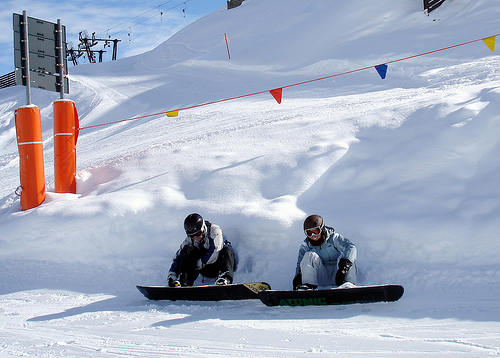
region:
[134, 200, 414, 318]
two snowboarders dismounting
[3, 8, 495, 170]
ski lift in ski area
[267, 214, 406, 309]
woman adjusts snowboard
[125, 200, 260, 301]
man adjusts snowboard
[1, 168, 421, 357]
couple adjusting snowboards in groomed snow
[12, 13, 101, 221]
rear view of sign in ski area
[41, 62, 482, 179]
flag marking barrier in ski area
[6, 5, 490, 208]
groomed ski run below ski lift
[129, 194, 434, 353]
couple relax on ski slope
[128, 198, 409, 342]
man and woman dressed in snowboarding gear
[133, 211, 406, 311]
Two snowboarders sitting down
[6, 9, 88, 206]
Sign attached to two orange supports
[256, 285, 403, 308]
Black snowboard with the word Atomic in green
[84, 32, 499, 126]
Rope with yellow, green and red flags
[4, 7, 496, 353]
Ski hill with many tracks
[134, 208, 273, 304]
Person with black helmet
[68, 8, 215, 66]
Two metal supports with hanging wires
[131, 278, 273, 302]
Black snowboard with yellow front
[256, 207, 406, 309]
Snowboarder with goggles with red lenses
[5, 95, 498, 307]
Snowboarders resting against snow bank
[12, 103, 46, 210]
the orange object sticking out of the snow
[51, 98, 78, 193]
the orange object sticking out of the snow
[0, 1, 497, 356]
the snow on the ground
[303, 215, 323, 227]
the helmet on the man's head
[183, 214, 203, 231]
the helmet on the man's head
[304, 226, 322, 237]
the protective eyewear on te man's face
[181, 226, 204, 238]
the protective eyewear on te man's face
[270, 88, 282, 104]
the red triangle flag hanging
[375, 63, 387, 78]
the blue triangle flag hanging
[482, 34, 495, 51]
the yellow triangle flag hanging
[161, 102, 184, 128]
a yellow flag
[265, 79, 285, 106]
a red pennant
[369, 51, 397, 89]
a blue pennant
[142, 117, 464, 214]
a small snow bank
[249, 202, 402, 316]
a person on a snowboard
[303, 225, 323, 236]
orange snow googles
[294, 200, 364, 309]
a person wearing a blue jacket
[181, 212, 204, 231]
a black helmet on head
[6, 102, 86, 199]
orange posts in the snow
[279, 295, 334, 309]
green lettering on the bottom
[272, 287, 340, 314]
Atomic on the bottom of the snowboard.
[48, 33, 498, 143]
Banner on the pole.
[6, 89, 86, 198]
There are two orange poles.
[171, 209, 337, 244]
The snowboarders are wearing helmets.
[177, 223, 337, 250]
The snowboarders are wearing goggles.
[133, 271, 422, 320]
Snowboards on the feet.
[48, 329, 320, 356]
Tracks in the snow.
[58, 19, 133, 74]
Ski lift over the hill.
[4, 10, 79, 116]
Back of a sign.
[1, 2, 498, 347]
Snow on the hill.